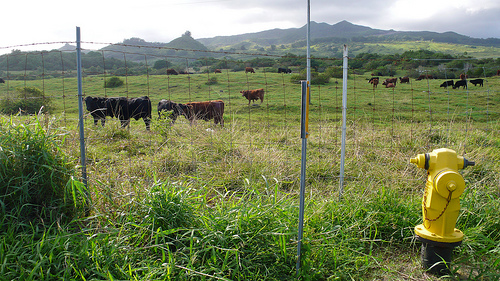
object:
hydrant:
[405, 145, 480, 249]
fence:
[80, 36, 371, 222]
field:
[125, 76, 484, 130]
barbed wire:
[58, 37, 492, 69]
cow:
[235, 84, 268, 106]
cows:
[79, 93, 153, 134]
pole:
[336, 43, 348, 201]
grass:
[100, 163, 218, 185]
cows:
[155, 96, 228, 133]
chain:
[419, 185, 456, 223]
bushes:
[2, 133, 82, 236]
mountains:
[198, 21, 499, 56]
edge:
[95, 46, 496, 59]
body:
[238, 88, 269, 107]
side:
[243, 86, 255, 105]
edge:
[335, 50, 340, 195]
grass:
[167, 206, 257, 276]